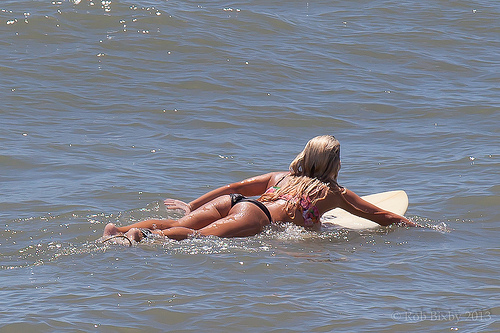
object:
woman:
[99, 132, 426, 246]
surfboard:
[320, 189, 410, 233]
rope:
[94, 224, 137, 248]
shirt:
[260, 177, 322, 226]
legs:
[120, 209, 247, 245]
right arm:
[335, 185, 423, 230]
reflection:
[0, 0, 237, 75]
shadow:
[316, 217, 346, 232]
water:
[1, 0, 499, 332]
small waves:
[40, 74, 386, 145]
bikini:
[226, 172, 322, 228]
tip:
[385, 189, 411, 205]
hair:
[263, 134, 339, 208]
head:
[289, 135, 342, 177]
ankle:
[138, 226, 154, 242]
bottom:
[218, 193, 273, 225]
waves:
[0, 0, 498, 333]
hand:
[413, 223, 440, 233]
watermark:
[403, 304, 492, 322]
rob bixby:
[404, 307, 463, 327]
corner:
[382, 286, 499, 332]